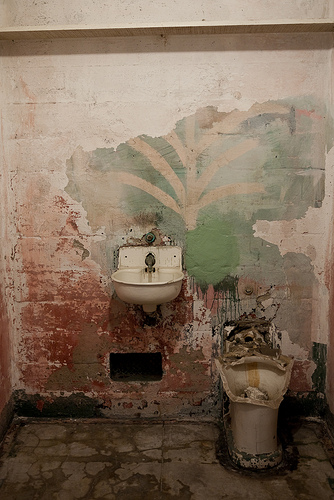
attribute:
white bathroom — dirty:
[19, 73, 302, 220]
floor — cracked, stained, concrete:
[2, 412, 332, 496]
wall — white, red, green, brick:
[1, 3, 332, 498]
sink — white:
[108, 236, 189, 312]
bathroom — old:
[0, 41, 332, 499]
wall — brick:
[9, 60, 330, 421]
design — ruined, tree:
[39, 101, 327, 372]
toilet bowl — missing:
[211, 352, 294, 469]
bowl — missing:
[106, 267, 184, 305]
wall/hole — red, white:
[3, 32, 317, 417]